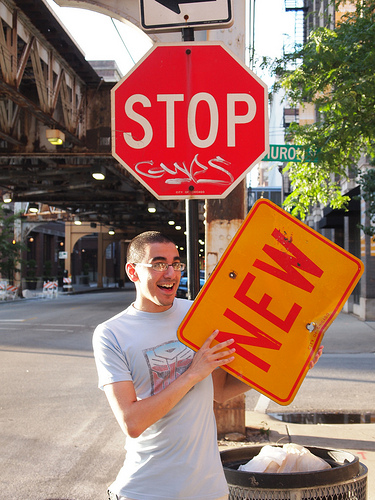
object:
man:
[92, 231, 324, 498]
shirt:
[93, 297, 231, 499]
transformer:
[143, 340, 196, 417]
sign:
[110, 41, 270, 201]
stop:
[123, 94, 256, 149]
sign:
[177, 198, 365, 407]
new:
[212, 228, 324, 372]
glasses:
[127, 263, 185, 273]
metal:
[219, 444, 368, 499]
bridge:
[0, 0, 203, 299]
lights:
[91, 170, 108, 185]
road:
[0, 282, 374, 498]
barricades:
[0, 276, 73, 302]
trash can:
[220, 446, 369, 499]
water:
[266, 410, 374, 426]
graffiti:
[135, 154, 234, 186]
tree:
[245, 0, 374, 242]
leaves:
[357, 78, 371, 109]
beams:
[0, 0, 205, 260]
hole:
[228, 272, 236, 280]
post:
[206, 0, 246, 443]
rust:
[206, 174, 246, 442]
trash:
[236, 443, 332, 470]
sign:
[260, 146, 320, 166]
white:
[136, 462, 146, 478]